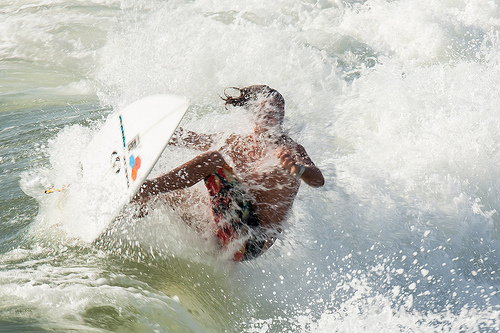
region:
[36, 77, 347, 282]
person is surfing in the ocean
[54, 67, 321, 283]
person is riding the wave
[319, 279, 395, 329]
water splashing up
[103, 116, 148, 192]
stickers on the surfboard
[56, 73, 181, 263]
white surfboard sticking out of the water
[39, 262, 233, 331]
wave in the ocean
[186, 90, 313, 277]
surfer's butt is touching the wave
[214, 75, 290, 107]
surfer has wet hair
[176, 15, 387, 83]
waves are crashing behind the surfer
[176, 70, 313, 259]
man in the ocean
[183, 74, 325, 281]
this is a man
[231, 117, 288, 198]
the man is bare chested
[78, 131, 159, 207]
this is a surfboard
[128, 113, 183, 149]
the surfboard is white in color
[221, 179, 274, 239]
this is a short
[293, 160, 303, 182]
this is a wrist band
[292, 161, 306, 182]
the band is white in color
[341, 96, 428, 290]
this is a water body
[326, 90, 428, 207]
the water is rough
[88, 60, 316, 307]
the boy is surfing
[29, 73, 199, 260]
the surfboard is white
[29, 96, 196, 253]
this is a surfboard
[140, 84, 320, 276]
this is a person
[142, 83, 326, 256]
this person is a surfer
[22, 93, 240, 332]
this is a wave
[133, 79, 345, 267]
this person is wearing shorts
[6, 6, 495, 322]
this is white water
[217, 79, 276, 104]
this is the person's hair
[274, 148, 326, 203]
this is a person's hand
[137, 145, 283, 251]
this is a person's leg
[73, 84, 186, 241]
this surfboard is white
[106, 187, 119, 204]
the surfboard is white in color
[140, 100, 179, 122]
the surfboard is wooden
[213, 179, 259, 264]
this is a swim suit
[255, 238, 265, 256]
the swim suit is black in color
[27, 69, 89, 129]
this is the water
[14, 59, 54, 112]
the water is blue in color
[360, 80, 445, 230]
this is the water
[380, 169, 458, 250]
the water is white in color